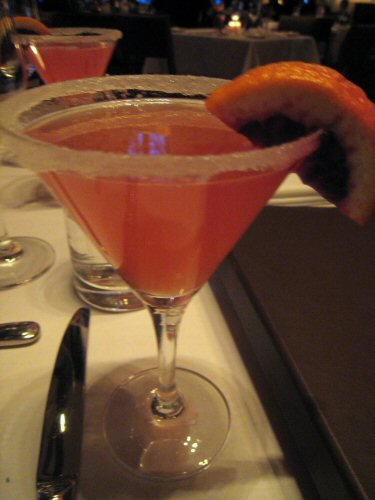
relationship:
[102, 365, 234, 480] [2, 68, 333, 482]
base of cup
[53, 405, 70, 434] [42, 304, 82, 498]
reflection on knife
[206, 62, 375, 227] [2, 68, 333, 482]
fruit on cup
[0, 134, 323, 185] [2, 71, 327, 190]
salt on rim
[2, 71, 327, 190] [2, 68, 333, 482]
rim of cup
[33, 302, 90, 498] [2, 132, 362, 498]
knife on table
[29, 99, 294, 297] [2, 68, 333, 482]
cocktail in cup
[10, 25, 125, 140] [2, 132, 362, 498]
drink on table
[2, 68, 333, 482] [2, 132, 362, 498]
cup on table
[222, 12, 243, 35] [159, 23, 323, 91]
lights on table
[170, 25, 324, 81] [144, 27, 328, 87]
tablecloth on table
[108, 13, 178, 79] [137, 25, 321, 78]
chair by table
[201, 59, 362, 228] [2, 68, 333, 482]
fruit on side of cup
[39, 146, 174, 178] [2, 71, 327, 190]
sugar on rim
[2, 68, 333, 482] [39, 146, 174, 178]
cup has sugar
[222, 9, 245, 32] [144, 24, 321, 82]
candle on table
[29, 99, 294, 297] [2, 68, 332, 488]
cocktail in cup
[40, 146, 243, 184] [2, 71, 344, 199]
salt on rim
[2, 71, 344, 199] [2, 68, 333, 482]
rim of cup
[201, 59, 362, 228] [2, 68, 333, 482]
fruit on cup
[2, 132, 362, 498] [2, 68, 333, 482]
table with cup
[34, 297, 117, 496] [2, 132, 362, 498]
silverware on table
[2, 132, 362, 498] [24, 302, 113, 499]
table with silverware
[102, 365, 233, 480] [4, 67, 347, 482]
base of glass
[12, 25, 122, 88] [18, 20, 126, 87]
drink in glass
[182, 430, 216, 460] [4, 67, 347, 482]
reflection on glass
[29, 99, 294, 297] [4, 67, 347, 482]
cocktail in glass